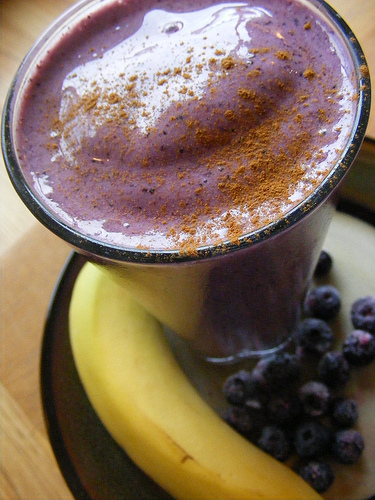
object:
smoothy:
[17, 3, 355, 249]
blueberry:
[304, 285, 341, 320]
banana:
[67, 259, 325, 499]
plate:
[0, 0, 370, 271]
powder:
[198, 124, 301, 205]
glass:
[18, 0, 355, 250]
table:
[0, 0, 375, 497]